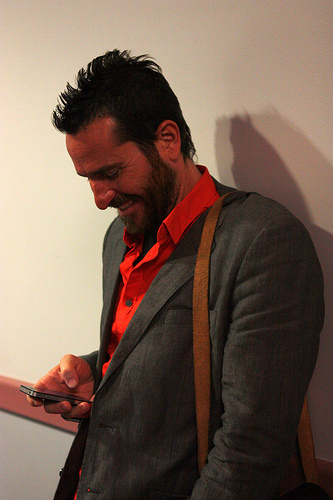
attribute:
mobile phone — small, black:
[19, 382, 93, 409]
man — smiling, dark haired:
[28, 45, 329, 499]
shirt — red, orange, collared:
[65, 156, 220, 499]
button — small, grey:
[123, 296, 133, 307]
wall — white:
[1, 0, 333, 499]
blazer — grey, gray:
[44, 175, 328, 499]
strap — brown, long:
[191, 187, 318, 488]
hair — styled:
[52, 49, 199, 165]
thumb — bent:
[58, 356, 78, 390]